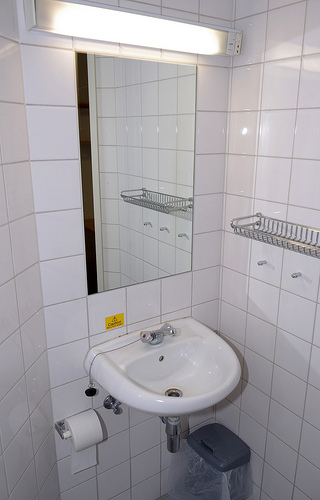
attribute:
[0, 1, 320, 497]
wall — white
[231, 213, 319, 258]
shelf — metal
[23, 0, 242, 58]
light — on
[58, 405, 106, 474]
toilet paper — rolled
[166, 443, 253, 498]
bag — plastic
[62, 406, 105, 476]
tissue roll — white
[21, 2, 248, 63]
holder — white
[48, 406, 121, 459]
holder — silver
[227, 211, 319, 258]
soap dish — silver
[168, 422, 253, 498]
trash — grey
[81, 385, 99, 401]
plug — black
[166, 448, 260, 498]
bag — plastic, clear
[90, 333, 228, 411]
sink — white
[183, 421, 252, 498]
garbage can — blue, plastic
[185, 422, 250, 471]
trash — gray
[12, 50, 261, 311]
wall — white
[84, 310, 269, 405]
sink — white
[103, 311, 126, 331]
sign — caution, yellow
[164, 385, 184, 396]
rusty drain — silver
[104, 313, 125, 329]
yellow sticker —  yellow  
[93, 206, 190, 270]
mirror —  long, hanging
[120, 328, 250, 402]
sink — white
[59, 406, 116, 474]
tissue — white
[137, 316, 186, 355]
faucet — silver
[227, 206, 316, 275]
rack — silver